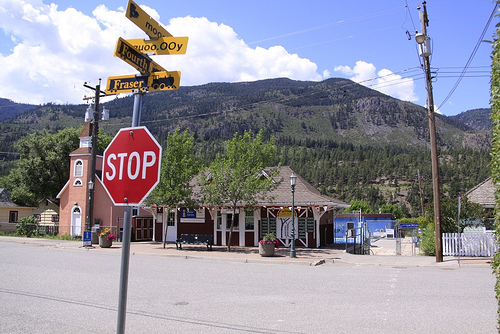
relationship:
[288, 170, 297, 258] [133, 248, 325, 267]
light post on sidewalk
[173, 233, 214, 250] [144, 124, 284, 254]
bench between trees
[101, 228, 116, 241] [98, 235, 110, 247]
flowers in planter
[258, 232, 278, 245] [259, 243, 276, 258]
flowers in planter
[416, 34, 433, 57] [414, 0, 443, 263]
transformer on utility pole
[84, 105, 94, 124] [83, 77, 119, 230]
transformer on utility pole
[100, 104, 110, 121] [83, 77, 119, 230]
transformer on utility pole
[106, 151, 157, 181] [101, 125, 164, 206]
lettering on sign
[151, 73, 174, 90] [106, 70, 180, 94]
train on sign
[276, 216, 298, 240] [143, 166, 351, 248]
sign on building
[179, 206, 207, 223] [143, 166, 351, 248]
sign on building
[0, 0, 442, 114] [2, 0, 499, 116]
clouds in sky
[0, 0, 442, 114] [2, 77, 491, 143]
clouds behind mountain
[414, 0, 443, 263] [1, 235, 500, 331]
utility pole on side of street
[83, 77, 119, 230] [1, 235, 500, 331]
utility pole on side of street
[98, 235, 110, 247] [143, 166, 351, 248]
planter in front of building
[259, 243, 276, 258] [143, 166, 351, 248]
planter in front of building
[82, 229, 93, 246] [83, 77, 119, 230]
sign at bottom of utility pole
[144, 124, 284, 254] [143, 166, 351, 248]
trees in front of building